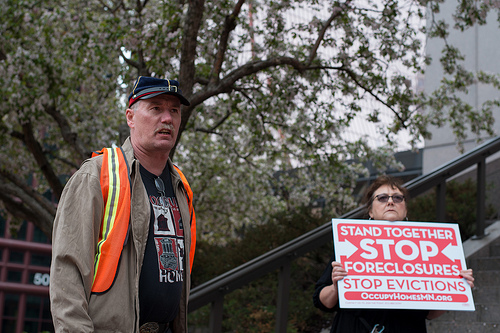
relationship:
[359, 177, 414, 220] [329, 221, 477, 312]
woman holding sign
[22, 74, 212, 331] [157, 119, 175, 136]
man has mustache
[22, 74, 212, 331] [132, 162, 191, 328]
man wearing shirt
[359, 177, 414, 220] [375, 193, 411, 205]
woman wearing sunglasses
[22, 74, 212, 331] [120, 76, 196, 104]
man wearing hat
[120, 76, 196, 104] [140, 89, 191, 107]
hat has bill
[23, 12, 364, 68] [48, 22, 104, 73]
tree has leaves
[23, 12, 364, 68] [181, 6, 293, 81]
tree has limbs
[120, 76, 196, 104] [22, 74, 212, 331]
hat on man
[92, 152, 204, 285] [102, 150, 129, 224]
vest has stripe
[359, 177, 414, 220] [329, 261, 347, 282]
woman has hand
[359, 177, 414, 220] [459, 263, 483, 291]
woman has hand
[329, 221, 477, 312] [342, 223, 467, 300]
sign has words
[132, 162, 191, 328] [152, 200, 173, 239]
shirt has square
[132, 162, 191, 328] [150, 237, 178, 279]
shirt had square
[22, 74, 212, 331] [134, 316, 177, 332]
man wearing belt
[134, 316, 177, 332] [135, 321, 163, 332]
belt has buckle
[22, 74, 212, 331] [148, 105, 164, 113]
man has eye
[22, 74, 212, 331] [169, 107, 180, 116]
man has eye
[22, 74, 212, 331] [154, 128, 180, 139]
man has mouth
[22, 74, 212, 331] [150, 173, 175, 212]
man has glasses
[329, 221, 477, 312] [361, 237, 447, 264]
sign says stop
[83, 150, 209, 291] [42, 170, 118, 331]
jacket has sleeve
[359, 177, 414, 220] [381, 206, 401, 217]
woman has mouth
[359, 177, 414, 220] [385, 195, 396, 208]
woman has nose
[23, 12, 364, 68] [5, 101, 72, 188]
tree has limbs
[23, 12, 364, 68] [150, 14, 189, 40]
tree has leaves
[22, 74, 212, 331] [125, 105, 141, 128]
man has ear